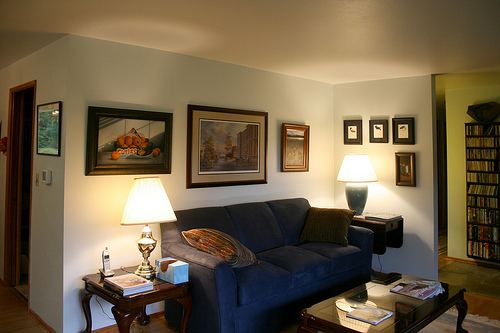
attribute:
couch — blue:
[159, 190, 365, 330]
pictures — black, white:
[340, 112, 420, 146]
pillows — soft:
[175, 225, 259, 275]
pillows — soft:
[299, 199, 360, 249]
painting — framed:
[81, 100, 176, 173]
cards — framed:
[342, 113, 363, 146]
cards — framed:
[366, 117, 386, 146]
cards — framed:
[395, 117, 419, 147]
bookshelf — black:
[460, 114, 498, 266]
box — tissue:
[154, 255, 190, 288]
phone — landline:
[99, 244, 116, 277]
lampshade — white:
[118, 173, 184, 231]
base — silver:
[133, 226, 162, 276]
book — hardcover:
[107, 267, 156, 304]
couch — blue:
[167, 195, 377, 330]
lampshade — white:
[336, 151, 381, 182]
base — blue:
[339, 185, 370, 218]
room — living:
[4, 2, 498, 331]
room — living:
[7, 31, 498, 328]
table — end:
[74, 255, 209, 332]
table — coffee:
[287, 263, 472, 331]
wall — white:
[74, 41, 337, 330]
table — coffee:
[299, 252, 486, 329]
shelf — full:
[460, 125, 499, 271]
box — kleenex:
[149, 253, 192, 288]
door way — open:
[11, 78, 48, 319]